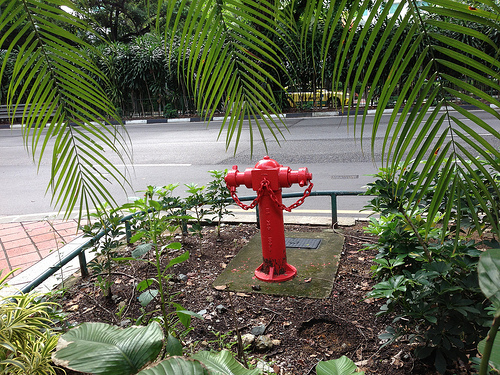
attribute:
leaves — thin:
[325, 1, 499, 220]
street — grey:
[25, 109, 281, 232]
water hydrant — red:
[215, 157, 323, 292]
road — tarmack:
[2, 115, 499, 215]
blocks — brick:
[4, 212, 82, 276]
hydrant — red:
[220, 118, 317, 268]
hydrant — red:
[224, 155, 313, 283]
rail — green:
[88, 195, 226, 257]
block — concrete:
[213, 225, 345, 301]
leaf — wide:
[48, 318, 163, 371]